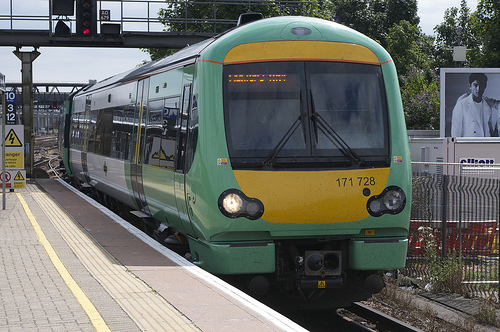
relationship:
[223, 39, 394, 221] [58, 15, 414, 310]
front of train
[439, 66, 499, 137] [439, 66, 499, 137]
ad on ad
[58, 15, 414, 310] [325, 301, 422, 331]
train on tracks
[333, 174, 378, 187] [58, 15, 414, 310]
numbers on train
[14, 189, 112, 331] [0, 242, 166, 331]
stripe on curb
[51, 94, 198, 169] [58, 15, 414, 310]
windows on train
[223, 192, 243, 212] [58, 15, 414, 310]
light on train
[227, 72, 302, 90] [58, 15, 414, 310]
display on train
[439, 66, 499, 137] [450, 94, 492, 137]
ad wearing shirt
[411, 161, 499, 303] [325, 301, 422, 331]
fence near tracks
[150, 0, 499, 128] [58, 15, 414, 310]
trees behind train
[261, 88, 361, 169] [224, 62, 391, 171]
wipers on windshield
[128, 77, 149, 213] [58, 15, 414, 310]
door on train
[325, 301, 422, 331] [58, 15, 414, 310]
tracks under train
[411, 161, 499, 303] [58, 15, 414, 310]
fence near train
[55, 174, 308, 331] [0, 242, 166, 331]
curb on curb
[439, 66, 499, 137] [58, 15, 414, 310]
ad near train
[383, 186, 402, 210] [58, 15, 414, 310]
light on train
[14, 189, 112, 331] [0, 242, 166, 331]
stripe painted on curb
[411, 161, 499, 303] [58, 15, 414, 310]
fence by train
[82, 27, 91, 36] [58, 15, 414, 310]
light above train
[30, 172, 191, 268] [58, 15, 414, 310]
shadow near train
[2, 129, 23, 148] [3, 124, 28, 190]
triangle on warning sign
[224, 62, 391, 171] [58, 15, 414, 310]
windshield on train